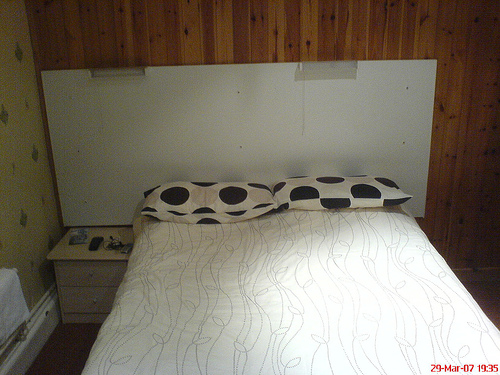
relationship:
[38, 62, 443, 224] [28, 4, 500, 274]
board on wall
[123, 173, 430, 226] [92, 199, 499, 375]
pillows on bed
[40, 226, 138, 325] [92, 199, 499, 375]
stand near bed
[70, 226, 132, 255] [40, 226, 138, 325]
items on stand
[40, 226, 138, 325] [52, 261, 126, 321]
stand has drawers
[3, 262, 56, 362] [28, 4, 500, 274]
heater on wall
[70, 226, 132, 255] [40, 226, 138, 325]
items on top of stand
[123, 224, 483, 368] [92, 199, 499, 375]
sheet on bed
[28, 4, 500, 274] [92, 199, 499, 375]
wall behind bed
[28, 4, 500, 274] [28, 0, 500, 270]
wall part wall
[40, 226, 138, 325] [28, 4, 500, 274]
stand near wall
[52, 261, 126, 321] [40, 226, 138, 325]
drawers on stand